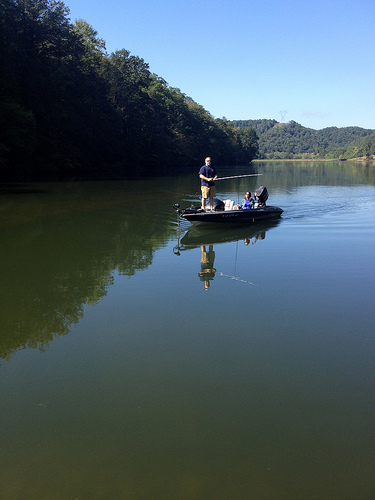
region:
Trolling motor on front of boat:
[170, 201, 184, 231]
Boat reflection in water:
[160, 220, 289, 253]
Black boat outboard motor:
[253, 185, 268, 206]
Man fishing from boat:
[198, 155, 262, 212]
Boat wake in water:
[132, 190, 361, 226]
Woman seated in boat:
[239, 187, 255, 212]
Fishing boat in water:
[170, 202, 285, 225]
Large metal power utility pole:
[277, 106, 288, 125]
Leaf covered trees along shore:
[4, 3, 260, 176]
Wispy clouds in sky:
[296, 106, 352, 119]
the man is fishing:
[172, 141, 296, 251]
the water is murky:
[151, 317, 246, 397]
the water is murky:
[102, 254, 183, 342]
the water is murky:
[255, 329, 361, 437]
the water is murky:
[50, 280, 195, 356]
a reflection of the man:
[180, 212, 244, 340]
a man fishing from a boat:
[170, 157, 363, 294]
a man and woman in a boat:
[169, 150, 290, 236]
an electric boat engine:
[170, 200, 187, 235]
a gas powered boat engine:
[250, 185, 268, 204]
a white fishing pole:
[216, 171, 267, 181]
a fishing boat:
[172, 204, 287, 226]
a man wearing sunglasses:
[201, 153, 215, 168]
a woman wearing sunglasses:
[235, 187, 255, 208]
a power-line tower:
[275, 108, 288, 124]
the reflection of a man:
[196, 239, 220, 296]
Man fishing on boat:
[173, 153, 286, 234]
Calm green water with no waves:
[10, 158, 373, 495]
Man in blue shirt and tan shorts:
[197, 156, 218, 214]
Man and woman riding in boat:
[173, 152, 284, 226]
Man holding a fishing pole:
[197, 149, 263, 218]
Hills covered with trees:
[220, 116, 373, 163]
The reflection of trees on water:
[4, 174, 196, 351]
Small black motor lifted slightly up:
[251, 182, 271, 210]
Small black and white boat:
[175, 199, 283, 229]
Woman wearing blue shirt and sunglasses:
[237, 188, 255, 213]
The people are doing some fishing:
[47, 107, 349, 482]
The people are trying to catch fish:
[22, 105, 357, 497]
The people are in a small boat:
[41, 97, 352, 493]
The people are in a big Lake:
[56, 102, 350, 492]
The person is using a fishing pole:
[45, 105, 360, 497]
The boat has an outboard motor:
[57, 90, 350, 469]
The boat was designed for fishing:
[62, 105, 350, 495]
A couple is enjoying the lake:
[78, 88, 360, 491]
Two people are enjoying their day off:
[76, 128, 367, 496]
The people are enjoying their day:
[70, 130, 334, 493]